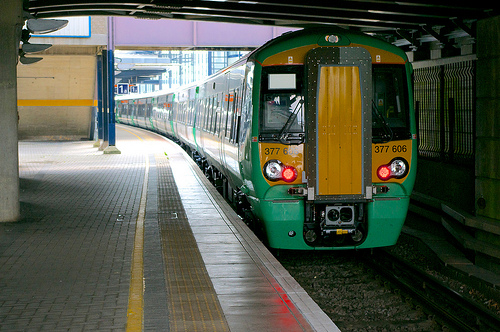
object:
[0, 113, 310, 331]
train platform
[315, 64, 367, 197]
door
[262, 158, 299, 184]
headlight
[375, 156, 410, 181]
headlight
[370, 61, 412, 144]
window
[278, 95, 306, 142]
windshield wiper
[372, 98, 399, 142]
windshield wiper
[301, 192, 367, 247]
connector assembly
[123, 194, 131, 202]
bricks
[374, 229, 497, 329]
track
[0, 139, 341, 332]
ground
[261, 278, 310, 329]
reflection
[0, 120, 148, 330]
loading zone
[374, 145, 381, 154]
numbers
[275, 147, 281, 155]
numbers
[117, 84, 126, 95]
sign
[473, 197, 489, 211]
hole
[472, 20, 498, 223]
concrete wall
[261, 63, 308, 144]
windows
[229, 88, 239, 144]
side windows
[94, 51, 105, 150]
poles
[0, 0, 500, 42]
bridge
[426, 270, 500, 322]
rails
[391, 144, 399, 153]
numbers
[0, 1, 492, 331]
train station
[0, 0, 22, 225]
column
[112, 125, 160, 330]
line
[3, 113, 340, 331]
sidewalk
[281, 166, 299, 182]
headlights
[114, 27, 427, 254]
subway train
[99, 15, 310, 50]
overpass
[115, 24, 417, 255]
subway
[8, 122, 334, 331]
zone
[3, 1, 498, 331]
station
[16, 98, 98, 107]
line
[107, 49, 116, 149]
pole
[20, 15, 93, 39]
sign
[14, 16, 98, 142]
wall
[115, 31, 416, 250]
light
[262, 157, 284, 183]
light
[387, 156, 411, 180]
light